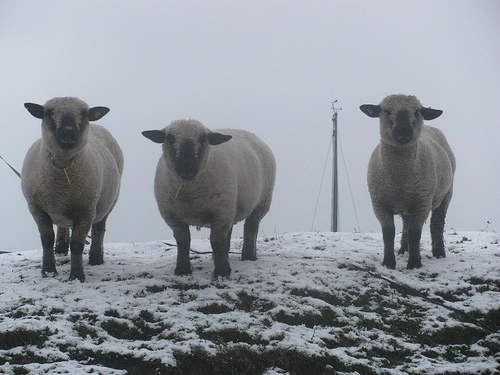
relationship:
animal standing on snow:
[358, 93, 456, 270] [7, 224, 499, 367]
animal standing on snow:
[141, 118, 276, 280] [7, 224, 499, 367]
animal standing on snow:
[20, 96, 125, 282] [7, 224, 499, 367]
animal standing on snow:
[141, 118, 276, 280] [291, 232, 358, 298]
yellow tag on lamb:
[59, 164, 76, 191] [10, 90, 125, 290]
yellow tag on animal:
[170, 184, 185, 205] [141, 118, 276, 280]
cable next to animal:
[160, 239, 499, 336] [358, 93, 456, 270]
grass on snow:
[0, 231, 497, 370] [7, 224, 499, 367]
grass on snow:
[386, 320, 416, 333] [7, 224, 499, 367]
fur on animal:
[19, 96, 125, 261] [19, 90, 125, 285]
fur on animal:
[366, 95, 453, 241] [333, 60, 479, 342]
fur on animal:
[142, 118, 276, 277] [127, 101, 314, 303]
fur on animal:
[19, 96, 118, 232] [19, 90, 125, 285]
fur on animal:
[142, 118, 276, 277] [139, 117, 274, 282]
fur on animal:
[366, 121, 456, 216] [354, 88, 460, 277]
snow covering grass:
[0, 232, 499, 375] [0, 280, 498, 372]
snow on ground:
[0, 232, 499, 375] [0, 263, 499, 373]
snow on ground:
[0, 232, 499, 375] [0, 229, 498, 373]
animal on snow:
[358, 93, 456, 270] [7, 224, 499, 367]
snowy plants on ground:
[307, 223, 403, 323] [0, 229, 498, 373]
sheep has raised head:
[134, 84, 467, 278] [354, 89, 446, 144]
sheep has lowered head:
[134, 84, 467, 278] [132, 111, 237, 181]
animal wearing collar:
[20, 96, 125, 282] [43, 146, 88, 185]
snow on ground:
[7, 224, 499, 367] [0, 229, 498, 373]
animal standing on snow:
[20, 96, 125, 282] [19, 278, 71, 293]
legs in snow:
[376, 207, 429, 273] [286, 220, 463, 350]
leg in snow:
[430, 218, 461, 266] [286, 220, 463, 350]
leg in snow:
[201, 213, 252, 288] [286, 220, 463, 350]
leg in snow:
[161, 226, 210, 294] [286, 220, 463, 350]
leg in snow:
[394, 210, 421, 260] [286, 220, 463, 350]